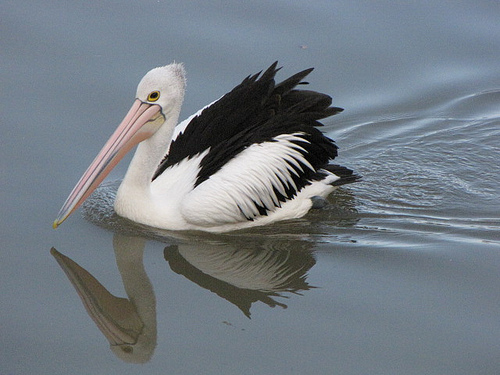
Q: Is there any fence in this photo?
A: No, there are no fences.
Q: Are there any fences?
A: No, there are no fences.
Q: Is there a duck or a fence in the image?
A: No, there are no fences or ducks.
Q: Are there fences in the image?
A: No, there are no fences.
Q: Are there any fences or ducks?
A: No, there are no fences or ducks.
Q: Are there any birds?
A: Yes, there is a bird.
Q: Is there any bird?
A: Yes, there is a bird.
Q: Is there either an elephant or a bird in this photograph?
A: Yes, there is a bird.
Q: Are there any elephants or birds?
A: Yes, there is a bird.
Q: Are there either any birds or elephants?
A: Yes, there is a bird.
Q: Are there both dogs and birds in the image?
A: No, there is a bird but no dogs.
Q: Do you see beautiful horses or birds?
A: Yes, there is a beautiful bird.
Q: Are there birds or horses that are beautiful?
A: Yes, the bird is beautiful.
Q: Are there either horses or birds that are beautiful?
A: Yes, the bird is beautiful.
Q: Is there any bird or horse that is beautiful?
A: Yes, the bird is beautiful.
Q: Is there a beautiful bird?
A: Yes, there is a beautiful bird.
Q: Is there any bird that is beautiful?
A: Yes, there is a bird that is beautiful.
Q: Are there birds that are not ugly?
A: Yes, there is an beautiful bird.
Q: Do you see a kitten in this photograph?
A: No, there are no kittens.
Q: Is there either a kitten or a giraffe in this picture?
A: No, there are no kittens or giraffes.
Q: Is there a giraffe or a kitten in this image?
A: No, there are no kittens or giraffes.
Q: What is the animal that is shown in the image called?
A: The animal is a bird.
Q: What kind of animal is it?
A: The animal is a bird.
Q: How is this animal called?
A: This is a bird.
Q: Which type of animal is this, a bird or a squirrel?
A: This is a bird.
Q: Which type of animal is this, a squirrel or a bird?
A: This is a bird.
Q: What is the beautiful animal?
A: The animal is a bird.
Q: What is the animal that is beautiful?
A: The animal is a bird.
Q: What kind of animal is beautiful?
A: The animal is a bird.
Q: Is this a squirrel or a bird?
A: This is a bird.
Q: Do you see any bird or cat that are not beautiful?
A: No, there is a bird but it is beautiful.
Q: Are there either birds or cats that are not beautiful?
A: No, there is a bird but it is beautiful.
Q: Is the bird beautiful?
A: Yes, the bird is beautiful.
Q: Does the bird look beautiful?
A: Yes, the bird is beautiful.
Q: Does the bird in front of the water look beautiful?
A: Yes, the bird is beautiful.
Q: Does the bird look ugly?
A: No, the bird is beautiful.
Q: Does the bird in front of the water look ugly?
A: No, the bird is beautiful.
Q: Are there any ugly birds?
A: No, there is a bird but it is beautiful.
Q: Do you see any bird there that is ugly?
A: No, there is a bird but it is beautiful.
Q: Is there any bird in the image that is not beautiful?
A: No, there is a bird but it is beautiful.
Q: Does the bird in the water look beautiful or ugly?
A: The bird is beautiful.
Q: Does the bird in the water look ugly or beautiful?
A: The bird is beautiful.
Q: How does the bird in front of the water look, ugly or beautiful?
A: The bird is beautiful.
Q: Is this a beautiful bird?
A: Yes, this is a beautiful bird.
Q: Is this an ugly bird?
A: No, this is a beautiful bird.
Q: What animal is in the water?
A: The bird is in the water.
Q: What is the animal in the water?
A: The animal is a bird.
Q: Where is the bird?
A: The bird is in the water.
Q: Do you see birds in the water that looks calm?
A: Yes, there is a bird in the water.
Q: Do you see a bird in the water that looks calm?
A: Yes, there is a bird in the water.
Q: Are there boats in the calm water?
A: No, there is a bird in the water.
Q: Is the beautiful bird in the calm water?
A: Yes, the bird is in the water.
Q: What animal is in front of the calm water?
A: The bird is in front of the water.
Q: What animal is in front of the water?
A: The bird is in front of the water.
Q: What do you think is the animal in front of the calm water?
A: The animal is a bird.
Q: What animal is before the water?
A: The animal is a bird.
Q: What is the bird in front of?
A: The bird is in front of the water.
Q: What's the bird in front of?
A: The bird is in front of the water.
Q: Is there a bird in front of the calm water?
A: Yes, there is a bird in front of the water.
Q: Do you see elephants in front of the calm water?
A: No, there is a bird in front of the water.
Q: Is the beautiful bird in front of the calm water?
A: Yes, the bird is in front of the water.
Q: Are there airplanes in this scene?
A: No, there are no airplanes.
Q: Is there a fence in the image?
A: No, there are no fences.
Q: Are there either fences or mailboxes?
A: No, there are no fences or mailboxes.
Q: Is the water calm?
A: Yes, the water is calm.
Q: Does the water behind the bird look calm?
A: Yes, the water is calm.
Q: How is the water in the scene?
A: The water is calm.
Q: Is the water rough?
A: No, the water is calm.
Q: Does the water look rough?
A: No, the water is calm.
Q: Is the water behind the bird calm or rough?
A: The water is calm.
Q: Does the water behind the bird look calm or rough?
A: The water is calm.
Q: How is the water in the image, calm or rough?
A: The water is calm.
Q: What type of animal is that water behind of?
A: The water is behind the bird.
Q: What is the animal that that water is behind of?
A: The animal is a bird.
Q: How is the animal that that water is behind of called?
A: The animal is a bird.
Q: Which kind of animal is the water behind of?
A: The water is behind the bird.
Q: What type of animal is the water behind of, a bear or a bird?
A: The water is behind a bird.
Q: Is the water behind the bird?
A: Yes, the water is behind the bird.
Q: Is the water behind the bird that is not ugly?
A: Yes, the water is behind the bird.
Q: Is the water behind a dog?
A: No, the water is behind the bird.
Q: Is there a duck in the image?
A: No, there are no ducks.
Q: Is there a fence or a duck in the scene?
A: No, there are no ducks or fences.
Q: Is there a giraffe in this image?
A: No, there are no giraffes.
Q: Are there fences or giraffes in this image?
A: No, there are no giraffes or fences.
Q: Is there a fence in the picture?
A: No, there are no fences.